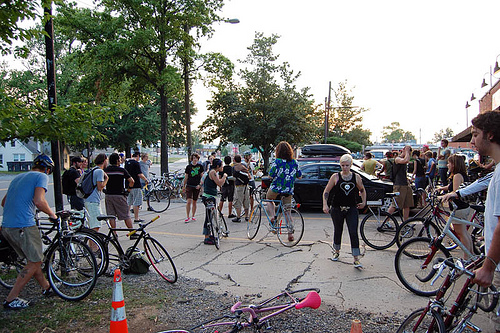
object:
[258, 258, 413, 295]
crack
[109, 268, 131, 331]
traffic cone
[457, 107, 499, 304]
man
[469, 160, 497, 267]
shirt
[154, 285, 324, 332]
bicycle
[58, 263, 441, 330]
gravel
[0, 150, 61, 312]
man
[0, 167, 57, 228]
shirt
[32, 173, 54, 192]
sleeve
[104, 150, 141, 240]
man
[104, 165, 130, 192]
shirt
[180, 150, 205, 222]
person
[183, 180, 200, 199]
shorts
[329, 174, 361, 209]
tank top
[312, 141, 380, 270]
woman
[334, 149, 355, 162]
hair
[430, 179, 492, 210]
person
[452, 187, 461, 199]
watch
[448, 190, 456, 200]
wrist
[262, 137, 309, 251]
man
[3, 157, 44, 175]
bushes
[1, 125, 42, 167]
house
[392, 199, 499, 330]
bicycle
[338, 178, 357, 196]
heart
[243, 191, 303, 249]
bike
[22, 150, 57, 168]
helmet